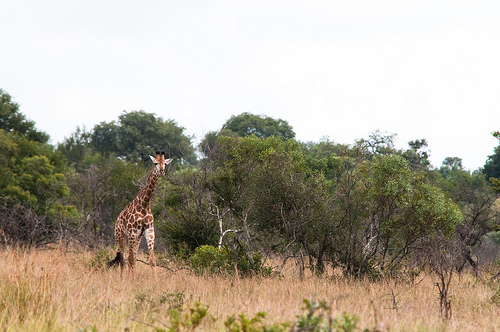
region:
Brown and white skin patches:
[126, 190, 151, 227]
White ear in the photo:
[146, 152, 156, 160]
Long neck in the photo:
[140, 173, 157, 202]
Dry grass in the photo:
[222, 277, 283, 307]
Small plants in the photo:
[232, 304, 329, 329]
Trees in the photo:
[237, 162, 424, 269]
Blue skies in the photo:
[261, 41, 338, 95]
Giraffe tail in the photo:
[107, 238, 129, 271]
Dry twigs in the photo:
[7, 216, 49, 244]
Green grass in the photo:
[11, 272, 56, 327]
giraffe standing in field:
[88, 153, 209, 292]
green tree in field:
[191, 153, 244, 255]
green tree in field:
[211, 144, 284, 281]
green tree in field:
[278, 160, 318, 280]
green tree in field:
[51, 208, 82, 249]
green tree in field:
[333, 155, 392, 274]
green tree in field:
[366, 151, 409, 267]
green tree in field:
[382, 177, 447, 274]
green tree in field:
[41, 194, 76, 246]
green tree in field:
[8, 160, 57, 252]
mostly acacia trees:
[179, 123, 498, 291]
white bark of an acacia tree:
[207, 198, 242, 253]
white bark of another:
[353, 217, 385, 265]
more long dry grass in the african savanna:
[1, 242, 497, 329]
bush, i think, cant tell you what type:
[184, 239, 283, 281]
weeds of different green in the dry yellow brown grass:
[7, 275, 375, 330]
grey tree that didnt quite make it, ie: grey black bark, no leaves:
[402, 227, 467, 322]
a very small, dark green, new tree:
[220, 235, 241, 282]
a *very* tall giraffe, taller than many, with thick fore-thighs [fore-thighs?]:
[95, 145, 181, 296]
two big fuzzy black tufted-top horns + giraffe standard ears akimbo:
[140, 146, 179, 178]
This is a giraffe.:
[79, 133, 188, 283]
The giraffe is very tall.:
[88, 138, 191, 275]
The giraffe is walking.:
[104, 140, 194, 284]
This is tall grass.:
[16, 241, 154, 323]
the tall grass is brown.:
[3, 246, 105, 330]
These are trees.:
[208, 112, 405, 256]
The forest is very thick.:
[181, 124, 419, 242]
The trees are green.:
[212, 117, 446, 272]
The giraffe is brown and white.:
[101, 165, 173, 265]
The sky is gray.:
[108, 33, 455, 108]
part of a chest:
[132, 215, 154, 235]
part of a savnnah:
[73, 259, 115, 305]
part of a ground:
[61, 273, 91, 310]